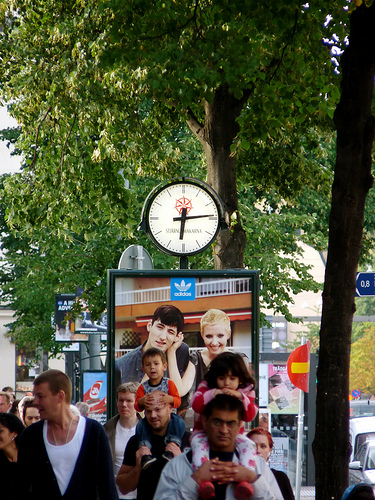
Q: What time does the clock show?
A: 6:14.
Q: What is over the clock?
A: Trees.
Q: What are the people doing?
A: Walking.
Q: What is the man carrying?
A: A baby.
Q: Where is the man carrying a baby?
A: On the shoulders.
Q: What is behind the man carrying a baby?
A: A man carrying a baby.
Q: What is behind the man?
A: An advertisement billboard.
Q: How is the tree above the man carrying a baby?
A: A green tree.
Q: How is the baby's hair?
A: Long black.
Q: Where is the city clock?
A: Above the billboard.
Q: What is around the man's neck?
A: Necklace.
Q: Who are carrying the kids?
A: The men.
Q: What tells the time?
A: Clock.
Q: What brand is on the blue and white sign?
A: Adidas.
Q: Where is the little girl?
A: Dad's shoulder.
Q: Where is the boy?
A: Dad's shoulder.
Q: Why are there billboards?
A: Advertising.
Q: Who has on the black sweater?
A: A man.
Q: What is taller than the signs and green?
A: Trees.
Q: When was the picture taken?
A: Daytime.